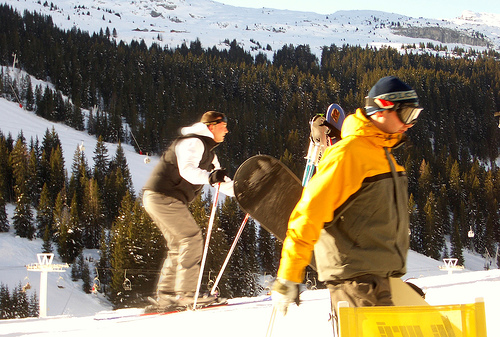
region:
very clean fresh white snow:
[77, 317, 179, 335]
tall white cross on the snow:
[18, 239, 71, 304]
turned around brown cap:
[192, 105, 241, 125]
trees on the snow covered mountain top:
[158, 13, 282, 50]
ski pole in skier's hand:
[194, 160, 224, 307]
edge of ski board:
[211, 148, 310, 228]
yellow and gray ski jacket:
[260, 130, 455, 302]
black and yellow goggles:
[388, 95, 435, 130]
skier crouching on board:
[106, 93, 245, 310]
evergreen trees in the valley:
[133, 45, 293, 117]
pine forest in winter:
[3, 5, 192, 110]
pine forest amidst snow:
[6, 10, 166, 140]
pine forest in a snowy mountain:
[4, 4, 166, 139]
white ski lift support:
[25, 255, 61, 319]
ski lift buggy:
[18, 268, 33, 293]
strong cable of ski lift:
[3, 261, 26, 272]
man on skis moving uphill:
[138, 104, 242, 310]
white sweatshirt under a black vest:
[152, 121, 219, 206]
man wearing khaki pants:
[138, 190, 202, 295]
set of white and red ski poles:
[191, 177, 240, 322]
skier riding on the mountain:
[124, 76, 468, 335]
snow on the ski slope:
[4, 57, 457, 279]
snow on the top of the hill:
[21, 2, 495, 58]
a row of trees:
[4, 5, 491, 259]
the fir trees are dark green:
[5, 8, 491, 273]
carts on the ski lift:
[5, 251, 495, 301]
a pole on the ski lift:
[27, 251, 60, 316]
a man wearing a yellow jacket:
[277, 108, 407, 279]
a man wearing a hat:
[355, 73, 422, 111]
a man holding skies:
[187, 166, 253, 308]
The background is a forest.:
[51, 45, 388, 117]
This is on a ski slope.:
[3, 14, 490, 296]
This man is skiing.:
[128, 92, 250, 322]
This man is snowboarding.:
[239, 125, 429, 334]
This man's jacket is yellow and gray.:
[299, 98, 429, 303]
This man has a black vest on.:
[142, 118, 232, 319]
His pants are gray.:
[125, 178, 222, 307]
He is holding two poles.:
[191, 161, 270, 313]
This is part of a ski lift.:
[13, 242, 86, 335]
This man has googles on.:
[343, 72, 441, 167]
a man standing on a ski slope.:
[117, 85, 257, 316]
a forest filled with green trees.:
[1, 3, 498, 250]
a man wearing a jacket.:
[254, 71, 441, 327]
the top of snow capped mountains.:
[1, 0, 497, 57]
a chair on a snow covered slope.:
[314, 292, 495, 334]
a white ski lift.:
[21, 242, 92, 317]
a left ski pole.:
[166, 152, 233, 317]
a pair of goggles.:
[380, 98, 438, 136]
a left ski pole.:
[204, 176, 269, 313]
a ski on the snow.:
[87, 283, 292, 334]